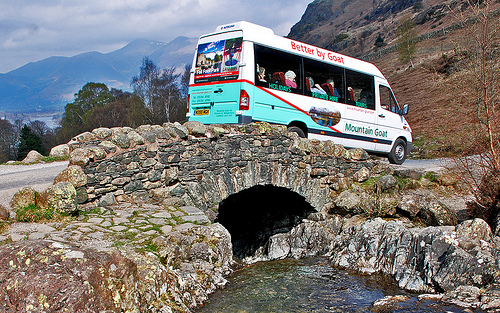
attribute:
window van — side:
[249, 44, 298, 99]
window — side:
[303, 60, 344, 104]